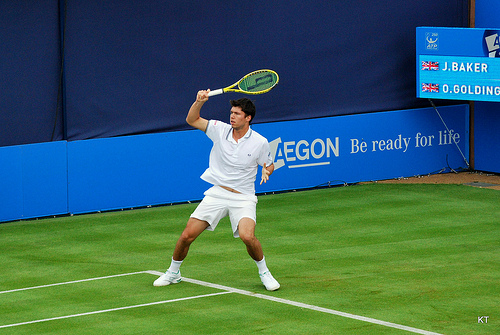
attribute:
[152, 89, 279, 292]
man — in motion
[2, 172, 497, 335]
court — green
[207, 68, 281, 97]
racket — yellow, white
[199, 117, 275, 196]
shirt — white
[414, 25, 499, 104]
scoreboard — blue, white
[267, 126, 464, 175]
sign — advertisement, sponsor, white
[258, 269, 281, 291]
shoe — white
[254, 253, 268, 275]
sock — white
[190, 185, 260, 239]
shorts — white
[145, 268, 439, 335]
line — white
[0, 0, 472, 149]
wall — dark blue, blue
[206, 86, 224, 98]
handle — white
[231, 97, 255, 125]
hair — black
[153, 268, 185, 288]
shoe — white